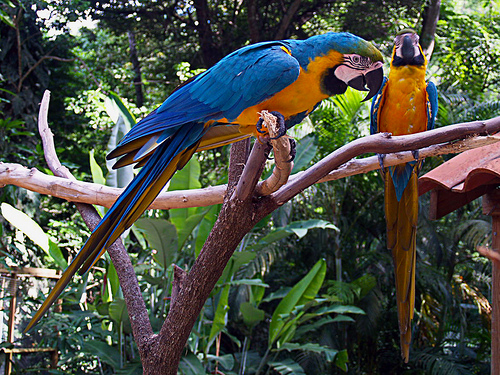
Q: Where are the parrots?
A: On the tree.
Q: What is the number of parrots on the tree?
A: Two.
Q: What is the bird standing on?
A: A tree.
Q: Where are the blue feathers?
A: On the birds.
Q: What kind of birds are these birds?
A: Macaws parrots.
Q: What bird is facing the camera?
A: The Macaw in the back.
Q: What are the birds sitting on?
A: Dried out tree branches.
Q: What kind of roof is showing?
A: Red clay tile roof.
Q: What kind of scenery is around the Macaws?
A: Jungle scenery.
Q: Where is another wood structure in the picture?
A: Behind the birds.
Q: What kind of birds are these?
A: Parrots.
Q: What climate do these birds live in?
A: Tropical.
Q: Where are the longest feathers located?
A: On the tails.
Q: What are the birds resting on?
A: Branches.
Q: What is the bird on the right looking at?
A: The camera.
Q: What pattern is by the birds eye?
A: Stripes.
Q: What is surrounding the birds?
A: Green plants.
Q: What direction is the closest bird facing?
A: To the right.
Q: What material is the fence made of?
A: Wood.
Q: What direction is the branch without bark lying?
A: Horizontally.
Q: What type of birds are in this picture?
A: Parrots.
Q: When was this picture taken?
A: Daytime.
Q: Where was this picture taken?
A: Zoo.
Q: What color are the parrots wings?
A: Blue.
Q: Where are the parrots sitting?
A: On branches.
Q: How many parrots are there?
A: 2.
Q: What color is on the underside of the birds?
A: Yellow.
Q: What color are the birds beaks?
A: Black.